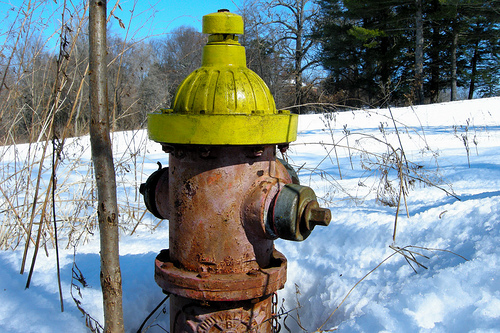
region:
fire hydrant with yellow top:
[180, 40, 233, 99]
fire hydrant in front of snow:
[201, 211, 221, 220]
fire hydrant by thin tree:
[101, 181, 123, 219]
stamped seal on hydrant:
[181, 313, 210, 324]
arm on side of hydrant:
[266, 188, 319, 238]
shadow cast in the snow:
[128, 251, 155, 282]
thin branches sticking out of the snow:
[331, 75, 381, 160]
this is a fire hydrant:
[121, 9, 315, 329]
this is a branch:
[304, 17, 376, 38]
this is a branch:
[248, 0, 290, 30]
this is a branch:
[355, 34, 399, 84]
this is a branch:
[420, 45, 465, 86]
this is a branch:
[450, 41, 493, 94]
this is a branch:
[461, 13, 487, 40]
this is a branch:
[19, 103, 91, 262]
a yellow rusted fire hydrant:
[135, 10, 335, 332]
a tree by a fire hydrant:
[2, 4, 147, 330]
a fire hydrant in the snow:
[137, 8, 333, 332]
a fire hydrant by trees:
[135, 10, 332, 332]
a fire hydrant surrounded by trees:
[139, 3, 334, 330]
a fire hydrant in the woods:
[136, 8, 331, 332]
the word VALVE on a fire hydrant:
[214, 311, 253, 325]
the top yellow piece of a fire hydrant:
[140, 9, 304, 146]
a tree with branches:
[245, 2, 352, 119]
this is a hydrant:
[148, 24, 321, 329]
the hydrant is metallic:
[157, 152, 294, 330]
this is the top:
[157, 12, 276, 129]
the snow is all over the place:
[379, 212, 486, 320]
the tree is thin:
[77, 106, 127, 168]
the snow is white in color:
[357, 267, 435, 325]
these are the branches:
[357, 123, 421, 198]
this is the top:
[157, 14, 266, 139]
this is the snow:
[334, 220, 379, 272]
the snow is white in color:
[407, 275, 477, 331]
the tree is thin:
[73, 106, 135, 183]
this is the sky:
[170, 2, 197, 22]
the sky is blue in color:
[164, 0, 194, 27]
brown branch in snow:
[389, 158, 405, 230]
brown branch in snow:
[389, 243, 424, 272]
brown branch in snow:
[365, 161, 458, 203]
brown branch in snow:
[341, 125, 356, 167]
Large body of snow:
[361, 203, 497, 310]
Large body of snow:
[343, 248, 470, 331]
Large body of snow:
[338, 239, 460, 330]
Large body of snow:
[416, 113, 498, 195]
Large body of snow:
[396, 283, 498, 326]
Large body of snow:
[393, 214, 494, 325]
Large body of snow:
[325, 245, 420, 327]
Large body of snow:
[366, 252, 456, 322]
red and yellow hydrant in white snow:
[141, 11, 328, 326]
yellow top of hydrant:
[143, 8, 298, 143]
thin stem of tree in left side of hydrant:
[87, 1, 120, 332]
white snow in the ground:
[0, 93, 497, 332]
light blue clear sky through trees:
[0, 2, 495, 97]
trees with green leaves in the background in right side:
[310, 5, 496, 112]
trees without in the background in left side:
[0, 25, 305, 140]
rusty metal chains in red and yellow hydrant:
[265, 295, 280, 330]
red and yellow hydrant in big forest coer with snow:
[135, 6, 325, 331]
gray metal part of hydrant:
[270, 181, 332, 245]